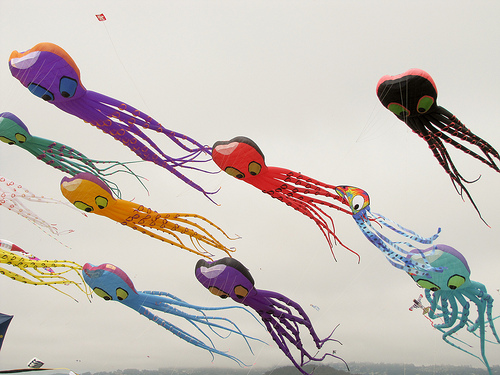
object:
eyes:
[56, 75, 79, 99]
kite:
[373, 67, 500, 227]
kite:
[0, 175, 87, 256]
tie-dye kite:
[333, 182, 444, 280]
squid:
[209, 135, 385, 264]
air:
[201, 24, 314, 75]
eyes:
[93, 195, 109, 211]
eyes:
[73, 199, 91, 215]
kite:
[59, 171, 242, 263]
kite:
[0, 112, 151, 203]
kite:
[6, 42, 222, 208]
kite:
[193, 253, 350, 373]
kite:
[80, 258, 270, 368]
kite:
[0, 250, 96, 307]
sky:
[0, 0, 498, 373]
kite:
[403, 240, 499, 374]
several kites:
[0, 41, 499, 373]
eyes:
[244, 158, 263, 176]